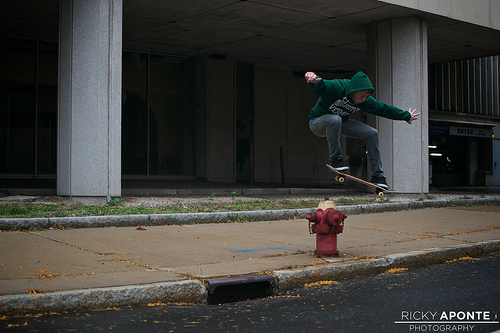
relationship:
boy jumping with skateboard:
[301, 67, 413, 190] [319, 153, 401, 203]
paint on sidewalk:
[227, 239, 294, 254] [0, 197, 500, 294]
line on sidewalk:
[217, 230, 335, 285] [257, 69, 402, 234]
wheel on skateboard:
[334, 173, 346, 188] [322, 157, 401, 206]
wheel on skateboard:
[374, 189, 389, 204] [322, 157, 401, 206]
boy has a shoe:
[301, 67, 413, 190] [328, 152, 351, 172]